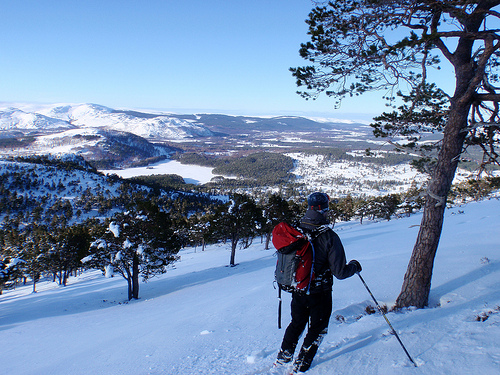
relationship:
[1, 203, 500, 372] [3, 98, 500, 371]
slope covered by snow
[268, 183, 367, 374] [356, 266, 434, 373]
man has ski pole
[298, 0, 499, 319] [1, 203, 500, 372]
tree on slope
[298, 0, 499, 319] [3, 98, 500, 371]
tree has snow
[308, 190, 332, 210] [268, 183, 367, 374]
helmet on man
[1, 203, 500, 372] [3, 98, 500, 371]
slope has snow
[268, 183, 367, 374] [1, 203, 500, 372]
man on slope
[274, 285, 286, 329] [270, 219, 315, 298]
strap from backpack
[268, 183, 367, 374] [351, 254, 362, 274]
man has gloves